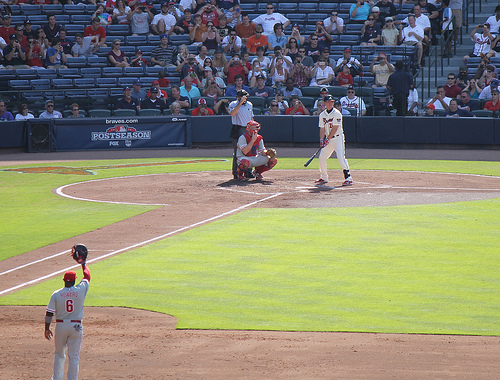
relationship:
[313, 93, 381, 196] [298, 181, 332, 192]
batter at home plate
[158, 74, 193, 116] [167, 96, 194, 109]
man with crossed arms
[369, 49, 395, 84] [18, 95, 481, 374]
man taking picture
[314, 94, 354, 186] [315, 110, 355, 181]
batter in uniform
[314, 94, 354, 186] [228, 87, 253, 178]
batter playing players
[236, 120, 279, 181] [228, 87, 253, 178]
catcher playing players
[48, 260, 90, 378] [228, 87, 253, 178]
players playing players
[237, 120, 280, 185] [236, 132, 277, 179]
catcher has on padding